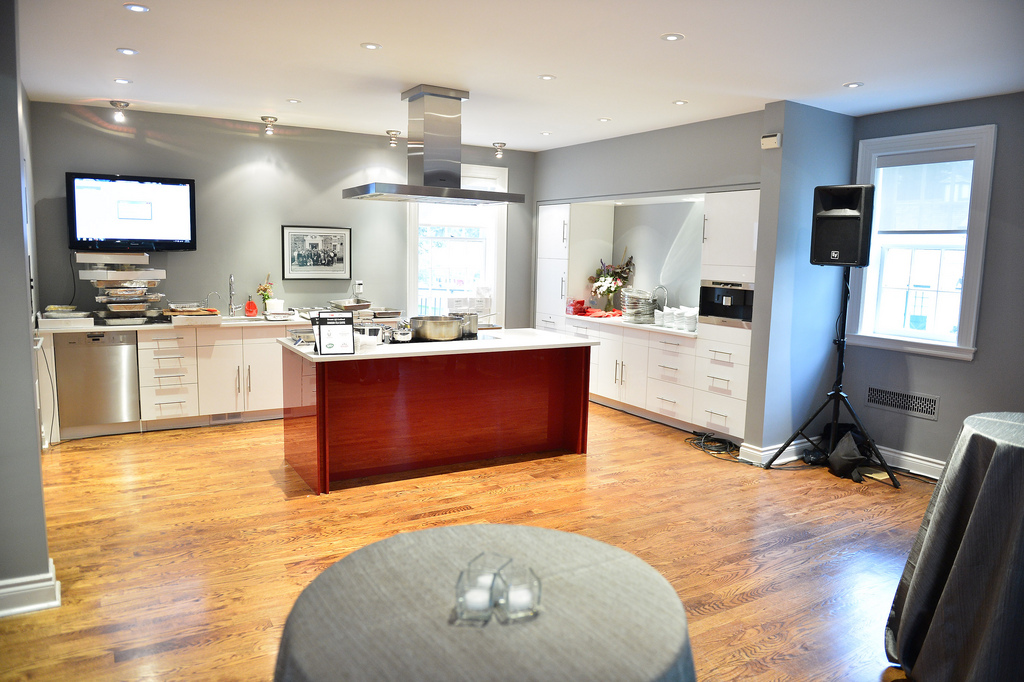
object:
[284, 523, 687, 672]
table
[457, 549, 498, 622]
candles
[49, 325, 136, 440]
dishwasher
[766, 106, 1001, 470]
wall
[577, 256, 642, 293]
flowers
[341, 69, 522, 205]
fan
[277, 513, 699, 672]
cloth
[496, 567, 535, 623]
holder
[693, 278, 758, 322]
microwave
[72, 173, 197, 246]
screen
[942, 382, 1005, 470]
wall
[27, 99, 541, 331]
wall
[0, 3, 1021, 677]
kitchen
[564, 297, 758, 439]
counter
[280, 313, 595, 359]
top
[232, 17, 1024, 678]
room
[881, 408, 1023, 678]
table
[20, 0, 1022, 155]
ceiling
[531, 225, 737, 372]
counter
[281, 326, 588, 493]
counter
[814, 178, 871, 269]
speaker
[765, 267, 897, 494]
stand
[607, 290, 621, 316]
vase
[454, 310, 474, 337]
pot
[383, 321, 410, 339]
pot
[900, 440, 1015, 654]
tablecloth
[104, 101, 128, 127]
light fixture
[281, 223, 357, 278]
frame